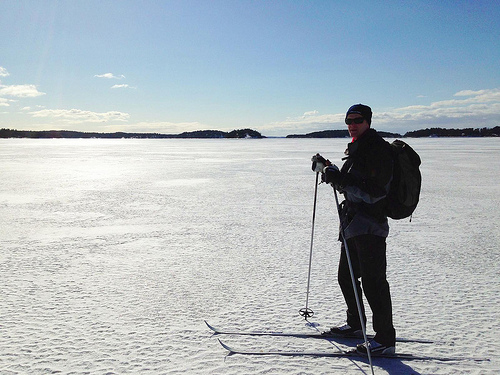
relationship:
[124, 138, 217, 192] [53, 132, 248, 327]
snow on ground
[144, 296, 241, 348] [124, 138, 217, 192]
tracks on snow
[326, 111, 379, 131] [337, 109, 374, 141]
sunglasses on face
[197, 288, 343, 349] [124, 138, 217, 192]
ski on snow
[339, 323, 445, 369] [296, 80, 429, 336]
shadow of man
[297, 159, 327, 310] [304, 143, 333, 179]
pole in hand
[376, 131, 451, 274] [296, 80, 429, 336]
bag on man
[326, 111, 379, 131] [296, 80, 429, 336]
sunglasses on man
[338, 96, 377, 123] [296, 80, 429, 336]
hat on man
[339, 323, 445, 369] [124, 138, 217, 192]
shadow on snow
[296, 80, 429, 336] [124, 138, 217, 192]
man in snow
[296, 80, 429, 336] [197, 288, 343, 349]
man on ski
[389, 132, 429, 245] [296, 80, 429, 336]
backpack on man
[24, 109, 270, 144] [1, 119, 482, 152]
tree on horizon